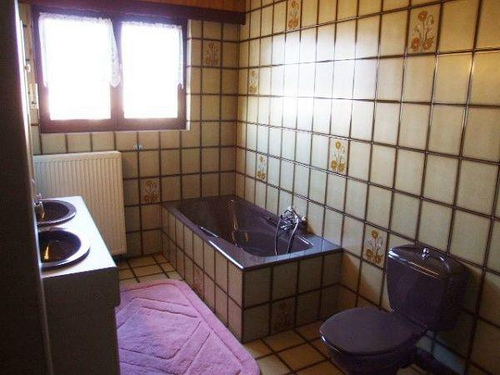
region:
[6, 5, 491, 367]
brown tiles around walls, floors and bathtub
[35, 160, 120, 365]
double sinks on vanity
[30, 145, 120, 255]
ridged white heater against wall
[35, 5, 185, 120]
short lace curtains over bright windows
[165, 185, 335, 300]
gray tub in corner of bathroom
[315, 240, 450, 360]
gray toilet with closed lid and tank against wall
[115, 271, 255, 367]
fluffy pink bathmat on floor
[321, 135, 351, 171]
special accent tiles of brown flowers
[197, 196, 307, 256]
contours on inside of tub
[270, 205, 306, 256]
hose around faucet on wall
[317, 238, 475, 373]
Purple toilet with seat down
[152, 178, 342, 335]
Purple ceramic bathtub with tiles surrounding it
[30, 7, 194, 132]
Windows with lace drapes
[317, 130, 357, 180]
Tile with flower print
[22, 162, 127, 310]
Double sink vanity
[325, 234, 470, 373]
Purple toilet with closed seat and top flush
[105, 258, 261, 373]
Pink bath mat laying on tile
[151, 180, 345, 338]
Bathtub with chrome fixtures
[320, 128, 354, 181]
Off-white tiles with flower print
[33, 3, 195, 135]
Sun shining through windows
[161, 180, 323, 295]
Bath tub in the room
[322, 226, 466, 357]
purple toilet in the bathroom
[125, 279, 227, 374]
purple rug on the floor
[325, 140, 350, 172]
floral pattern on the tile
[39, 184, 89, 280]
dual sinks in the bathroom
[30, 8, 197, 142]
window in the bathroom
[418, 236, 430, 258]
chrome button a toilet tank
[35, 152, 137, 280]
radiator in the bathroom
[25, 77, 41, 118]
light on the bathroom wall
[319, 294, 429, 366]
purple lid on a toilet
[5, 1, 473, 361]
black toilet, bath tub and sink in bathroom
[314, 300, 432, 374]
black half of toilet on tile floor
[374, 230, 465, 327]
black tank of toilet in bathroom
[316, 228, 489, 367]
black toilet in bathroom with lid down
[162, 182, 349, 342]
black tiled bath tub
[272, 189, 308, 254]
silver knobs in bath tub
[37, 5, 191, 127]
light shining through windows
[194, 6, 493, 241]
white and black tile walls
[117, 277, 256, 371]
lavender bathroom rug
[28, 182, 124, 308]
double bathroom sink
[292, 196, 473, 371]
purple toilet on wall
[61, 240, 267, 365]
purple bathroom carpet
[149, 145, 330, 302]
dark purple bath tub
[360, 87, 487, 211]
light brown wall tiles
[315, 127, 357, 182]
flower tile on wall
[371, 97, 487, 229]
tile has dark brown grout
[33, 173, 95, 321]
purple double sink basin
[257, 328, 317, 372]
brown tile on floor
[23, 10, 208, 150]
two pane window on side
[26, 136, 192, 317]
white radiator against wall